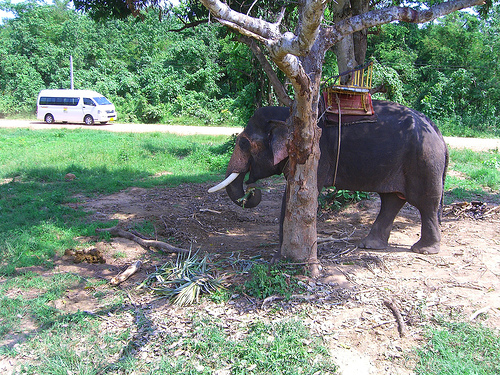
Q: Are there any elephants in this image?
A: Yes, there is an elephant.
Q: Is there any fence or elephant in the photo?
A: Yes, there is an elephant.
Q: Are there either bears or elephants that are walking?
A: Yes, the elephant is walking.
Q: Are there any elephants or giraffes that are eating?
A: Yes, the elephant is eating.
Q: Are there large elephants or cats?
A: Yes, there is a large elephant.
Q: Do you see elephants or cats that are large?
A: Yes, the elephant is large.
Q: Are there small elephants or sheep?
A: Yes, there is a small elephant.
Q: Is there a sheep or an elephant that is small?
A: Yes, the elephant is small.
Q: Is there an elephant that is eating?
A: Yes, there is an elephant that is eating.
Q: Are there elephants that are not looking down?
A: Yes, there is an elephant that is eating.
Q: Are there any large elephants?
A: Yes, there is a large elephant.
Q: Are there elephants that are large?
A: Yes, there is an elephant that is large.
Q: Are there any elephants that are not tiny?
A: Yes, there is a large elephant.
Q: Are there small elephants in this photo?
A: Yes, there is a small elephant.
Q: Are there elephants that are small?
A: Yes, there is an elephant that is small.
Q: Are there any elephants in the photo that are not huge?
A: Yes, there is a small elephant.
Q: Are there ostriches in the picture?
A: No, there are no ostriches.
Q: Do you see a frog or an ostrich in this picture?
A: No, there are no ostriches or frogs.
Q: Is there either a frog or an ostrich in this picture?
A: No, there are no ostriches or frogs.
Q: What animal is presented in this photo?
A: The animal is an elephant.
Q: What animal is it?
A: The animal is an elephant.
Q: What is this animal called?
A: This is an elephant.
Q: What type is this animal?
A: This is an elephant.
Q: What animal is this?
A: This is an elephant.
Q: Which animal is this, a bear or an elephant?
A: This is an elephant.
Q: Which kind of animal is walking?
A: The animal is an elephant.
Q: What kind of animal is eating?
A: The animal is an elephant.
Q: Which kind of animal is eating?
A: The animal is an elephant.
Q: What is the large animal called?
A: The animal is an elephant.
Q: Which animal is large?
A: The animal is an elephant.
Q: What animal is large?
A: The animal is an elephant.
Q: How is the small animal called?
A: The animal is an elephant.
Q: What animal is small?
A: The animal is an elephant.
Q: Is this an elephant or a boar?
A: This is an elephant.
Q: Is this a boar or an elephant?
A: This is an elephant.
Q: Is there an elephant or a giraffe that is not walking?
A: No, there is an elephant but it is walking.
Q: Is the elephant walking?
A: Yes, the elephant is walking.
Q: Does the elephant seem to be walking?
A: Yes, the elephant is walking.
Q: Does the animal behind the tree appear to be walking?
A: Yes, the elephant is walking.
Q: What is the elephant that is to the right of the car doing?
A: The elephant is walking.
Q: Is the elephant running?
A: No, the elephant is walking.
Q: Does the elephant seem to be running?
A: No, the elephant is walking.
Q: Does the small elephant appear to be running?
A: No, the elephant is walking.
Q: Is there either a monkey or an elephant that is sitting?
A: No, there is an elephant but it is walking.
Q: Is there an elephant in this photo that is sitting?
A: No, there is an elephant but it is walking.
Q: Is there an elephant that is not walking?
A: No, there is an elephant but it is walking.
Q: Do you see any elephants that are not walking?
A: No, there is an elephant but it is walking.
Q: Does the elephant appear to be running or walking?
A: The elephant is walking.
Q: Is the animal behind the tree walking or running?
A: The elephant is walking.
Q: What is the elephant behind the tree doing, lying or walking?
A: The elephant is walking.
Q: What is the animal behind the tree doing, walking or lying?
A: The elephant is walking.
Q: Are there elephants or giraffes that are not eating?
A: No, there is an elephant but it is eating.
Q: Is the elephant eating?
A: Yes, the elephant is eating.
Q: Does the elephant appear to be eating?
A: Yes, the elephant is eating.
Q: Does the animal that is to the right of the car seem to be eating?
A: Yes, the elephant is eating.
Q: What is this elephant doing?
A: The elephant is eating.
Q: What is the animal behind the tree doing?
A: The elephant is eating.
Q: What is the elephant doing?
A: The elephant is eating.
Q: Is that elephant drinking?
A: No, the elephant is eating.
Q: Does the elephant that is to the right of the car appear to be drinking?
A: No, the elephant is eating.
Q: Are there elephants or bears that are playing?
A: No, there is an elephant but it is eating.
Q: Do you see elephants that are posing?
A: No, there is an elephant but it is eating.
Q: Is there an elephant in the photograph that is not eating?
A: No, there is an elephant but it is eating.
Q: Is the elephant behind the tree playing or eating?
A: The elephant is eating.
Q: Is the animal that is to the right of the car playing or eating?
A: The elephant is eating.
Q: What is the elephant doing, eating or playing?
A: The elephant is eating.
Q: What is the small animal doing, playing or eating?
A: The elephant is eating.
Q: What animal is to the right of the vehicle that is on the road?
A: The animal is an elephant.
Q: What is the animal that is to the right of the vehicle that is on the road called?
A: The animal is an elephant.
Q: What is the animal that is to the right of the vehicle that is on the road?
A: The animal is an elephant.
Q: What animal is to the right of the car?
A: The animal is an elephant.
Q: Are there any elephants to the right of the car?
A: Yes, there is an elephant to the right of the car.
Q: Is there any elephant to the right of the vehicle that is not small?
A: Yes, there is an elephant to the right of the car.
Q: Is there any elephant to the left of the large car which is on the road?
A: No, the elephant is to the right of the car.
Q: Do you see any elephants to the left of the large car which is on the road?
A: No, the elephant is to the right of the car.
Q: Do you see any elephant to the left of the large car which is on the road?
A: No, the elephant is to the right of the car.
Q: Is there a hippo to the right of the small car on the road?
A: No, there is an elephant to the right of the car.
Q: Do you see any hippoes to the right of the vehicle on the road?
A: No, there is an elephant to the right of the car.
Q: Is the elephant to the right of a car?
A: Yes, the elephant is to the right of a car.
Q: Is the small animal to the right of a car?
A: Yes, the elephant is to the right of a car.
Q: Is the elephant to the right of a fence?
A: No, the elephant is to the right of a car.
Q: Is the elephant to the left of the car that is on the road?
A: No, the elephant is to the right of the car.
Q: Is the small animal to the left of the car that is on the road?
A: No, the elephant is to the right of the car.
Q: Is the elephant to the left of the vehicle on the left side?
A: No, the elephant is to the right of the car.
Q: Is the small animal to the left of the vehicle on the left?
A: No, the elephant is to the right of the car.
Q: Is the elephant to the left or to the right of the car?
A: The elephant is to the right of the car.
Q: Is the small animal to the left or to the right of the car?
A: The elephant is to the right of the car.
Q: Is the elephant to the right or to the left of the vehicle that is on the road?
A: The elephant is to the right of the car.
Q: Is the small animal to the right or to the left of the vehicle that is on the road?
A: The elephant is to the right of the car.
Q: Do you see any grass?
A: Yes, there is grass.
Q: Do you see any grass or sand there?
A: Yes, there is grass.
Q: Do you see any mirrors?
A: No, there are no mirrors.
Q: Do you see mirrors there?
A: No, there are no mirrors.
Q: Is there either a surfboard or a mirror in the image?
A: No, there are no mirrors or surfboards.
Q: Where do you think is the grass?
A: The grass is on the ground.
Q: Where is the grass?
A: The grass is on the ground.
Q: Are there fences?
A: No, there are no fences.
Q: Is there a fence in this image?
A: No, there are no fences.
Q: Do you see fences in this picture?
A: No, there are no fences.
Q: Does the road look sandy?
A: Yes, the road is sandy.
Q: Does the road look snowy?
A: No, the road is sandy.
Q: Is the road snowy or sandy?
A: The road is sandy.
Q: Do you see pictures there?
A: No, there are no pictures.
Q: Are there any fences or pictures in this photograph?
A: No, there are no pictures or fences.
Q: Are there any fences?
A: No, there are no fences.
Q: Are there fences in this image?
A: No, there are no fences.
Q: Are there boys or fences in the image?
A: No, there are no fences or boys.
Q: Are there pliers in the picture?
A: No, there are no pliers.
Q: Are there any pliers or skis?
A: No, there are no pliers or skis.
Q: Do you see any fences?
A: No, there are no fences.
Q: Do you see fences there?
A: No, there are no fences.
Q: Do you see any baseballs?
A: No, there are no baseballs.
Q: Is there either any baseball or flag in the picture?
A: No, there are no baseballs or flags.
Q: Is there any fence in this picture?
A: No, there are no fences.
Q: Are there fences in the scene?
A: No, there are no fences.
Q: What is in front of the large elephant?
A: The tree is in front of the elephant.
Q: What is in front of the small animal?
A: The tree is in front of the elephant.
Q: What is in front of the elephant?
A: The tree is in front of the elephant.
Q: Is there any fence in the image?
A: No, there are no fences.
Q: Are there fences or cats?
A: No, there are no fences or cats.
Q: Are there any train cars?
A: No, there are no train cars.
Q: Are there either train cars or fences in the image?
A: No, there are no train cars or fences.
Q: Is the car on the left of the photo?
A: Yes, the car is on the left of the image.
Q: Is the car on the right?
A: No, the car is on the left of the image.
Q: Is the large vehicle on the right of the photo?
A: No, the car is on the left of the image.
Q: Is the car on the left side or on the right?
A: The car is on the left of the image.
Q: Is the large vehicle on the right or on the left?
A: The car is on the left of the image.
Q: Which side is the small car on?
A: The car is on the left of the image.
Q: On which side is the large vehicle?
A: The car is on the left of the image.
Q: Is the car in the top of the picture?
A: Yes, the car is in the top of the image.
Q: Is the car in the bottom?
A: No, the car is in the top of the image.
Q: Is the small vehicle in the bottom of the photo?
A: No, the car is in the top of the image.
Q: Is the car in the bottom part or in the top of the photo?
A: The car is in the top of the image.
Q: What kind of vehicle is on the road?
A: The vehicle is a car.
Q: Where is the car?
A: The car is on the road.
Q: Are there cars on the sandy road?
A: Yes, there is a car on the road.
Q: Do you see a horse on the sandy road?
A: No, there is a car on the road.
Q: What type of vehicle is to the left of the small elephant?
A: The vehicle is a car.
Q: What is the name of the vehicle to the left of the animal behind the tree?
A: The vehicle is a car.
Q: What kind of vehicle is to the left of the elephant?
A: The vehicle is a car.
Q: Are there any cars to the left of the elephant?
A: Yes, there is a car to the left of the elephant.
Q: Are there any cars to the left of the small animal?
A: Yes, there is a car to the left of the elephant.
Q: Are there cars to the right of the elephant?
A: No, the car is to the left of the elephant.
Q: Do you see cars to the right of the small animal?
A: No, the car is to the left of the elephant.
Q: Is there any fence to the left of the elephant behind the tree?
A: No, there is a car to the left of the elephant.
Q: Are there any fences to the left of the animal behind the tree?
A: No, there is a car to the left of the elephant.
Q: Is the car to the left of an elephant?
A: Yes, the car is to the left of an elephant.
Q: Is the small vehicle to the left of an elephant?
A: Yes, the car is to the left of an elephant.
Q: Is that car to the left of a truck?
A: No, the car is to the left of an elephant.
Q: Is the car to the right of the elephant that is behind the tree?
A: No, the car is to the left of the elephant.